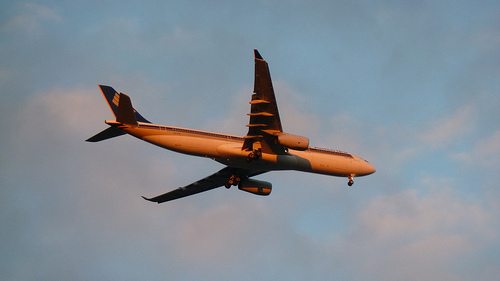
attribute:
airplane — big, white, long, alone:
[84, 49, 377, 205]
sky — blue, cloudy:
[0, 0, 500, 281]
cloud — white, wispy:
[39, 91, 179, 185]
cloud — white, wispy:
[371, 196, 470, 267]